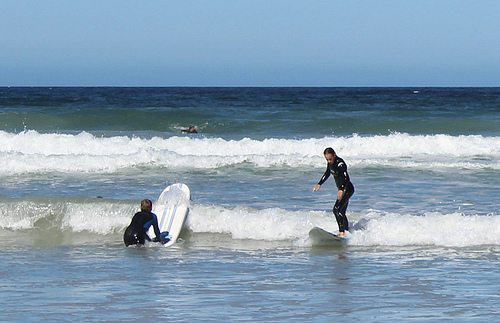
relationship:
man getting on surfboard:
[118, 195, 168, 249] [146, 177, 195, 249]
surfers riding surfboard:
[312, 147, 356, 238] [306, 226, 349, 246]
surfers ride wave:
[312, 147, 356, 238] [0, 126, 499, 247]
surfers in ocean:
[109, 148, 352, 252] [5, 90, 493, 323]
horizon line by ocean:
[5, 86, 498, 87] [5, 90, 493, 323]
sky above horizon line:
[1, 2, 499, 86] [5, 86, 498, 87]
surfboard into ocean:
[146, 177, 195, 249] [5, 90, 493, 323]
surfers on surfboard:
[312, 147, 356, 238] [306, 226, 349, 246]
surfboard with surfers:
[306, 226, 349, 246] [312, 147, 356, 238]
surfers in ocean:
[312, 147, 356, 238] [5, 90, 493, 323]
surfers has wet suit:
[312, 147, 356, 238] [317, 157, 360, 234]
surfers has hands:
[312, 147, 356, 238] [312, 182, 349, 202]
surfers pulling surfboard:
[312, 147, 356, 238] [306, 226, 349, 246]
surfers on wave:
[312, 147, 356, 238] [2, 126, 498, 172]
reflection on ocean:
[299, 243, 348, 265] [0, 86, 499, 323]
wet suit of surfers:
[123, 210, 161, 246] [312, 147, 356, 238]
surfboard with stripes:
[146, 177, 195, 249] [157, 184, 186, 232]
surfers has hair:
[312, 147, 356, 238] [324, 147, 335, 153]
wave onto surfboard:
[2, 126, 498, 172] [306, 226, 349, 246]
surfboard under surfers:
[306, 226, 349, 246] [312, 147, 356, 238]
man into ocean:
[118, 195, 168, 249] [5, 90, 493, 323]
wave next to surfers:
[0, 126, 499, 247] [109, 148, 352, 252]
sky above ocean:
[1, 2, 499, 86] [5, 90, 493, 323]